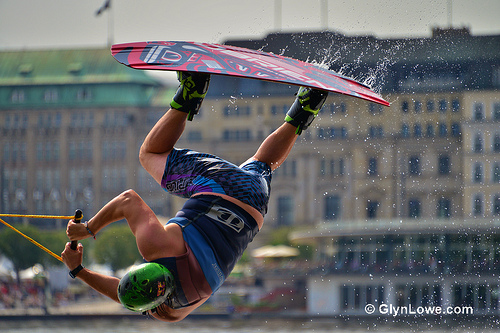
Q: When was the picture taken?
A: Daytime.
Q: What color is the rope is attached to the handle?
A: Yellow.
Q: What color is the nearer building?
A: White.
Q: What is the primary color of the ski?
A: Pink.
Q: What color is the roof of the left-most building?
A: Green.